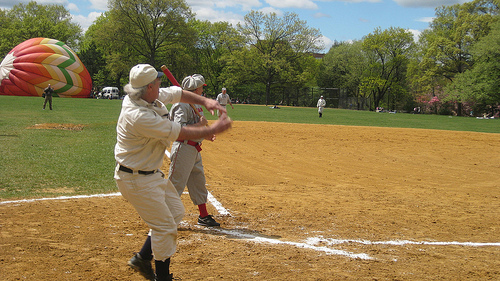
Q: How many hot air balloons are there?
A: One.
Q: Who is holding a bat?
A: A baseball player.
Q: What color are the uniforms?
A: White.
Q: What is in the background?
A: A hot air balloon.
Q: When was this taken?
A: During the day.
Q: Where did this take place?
A: A baseball diamond.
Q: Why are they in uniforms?
A: They're playing baseball.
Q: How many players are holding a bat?
A: One.